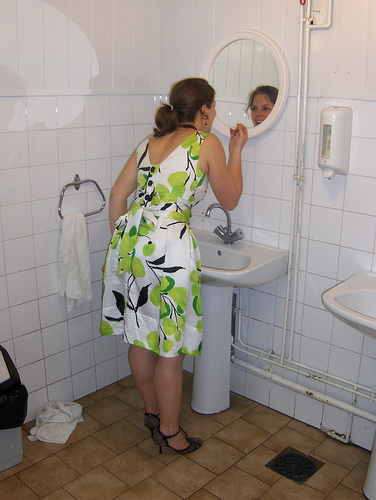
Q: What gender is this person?
A: Female.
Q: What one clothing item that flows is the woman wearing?
A: Dress.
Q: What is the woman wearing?
A: A green, black, and white party dress.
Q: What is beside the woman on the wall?
A: A towel holder with a towel on it.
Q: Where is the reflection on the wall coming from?
A: The mirror.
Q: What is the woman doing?
A: Fixing her makeup.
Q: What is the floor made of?
A: Tiles.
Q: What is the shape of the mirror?
A: Round.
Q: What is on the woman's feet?
A: High heels.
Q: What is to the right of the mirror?
A: Water pipes.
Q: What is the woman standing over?
A: A sink.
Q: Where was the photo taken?
A: In a restroom.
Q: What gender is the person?
A: Female.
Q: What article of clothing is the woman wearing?
A: A dress.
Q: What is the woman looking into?
A: A mirror.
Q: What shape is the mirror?
A: Round.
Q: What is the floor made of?
A: Tile.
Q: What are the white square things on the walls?
A: Tiles.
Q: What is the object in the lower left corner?
A: A waste basket.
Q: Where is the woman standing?
A: In front of a mirror.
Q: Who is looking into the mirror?
A: A woman.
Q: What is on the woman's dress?
A: Leaves.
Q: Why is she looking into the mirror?
A: Makeup.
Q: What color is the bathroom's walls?
A: White.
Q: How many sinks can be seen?
A: Two.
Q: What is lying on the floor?
A: A towel.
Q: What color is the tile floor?
A: Brown.